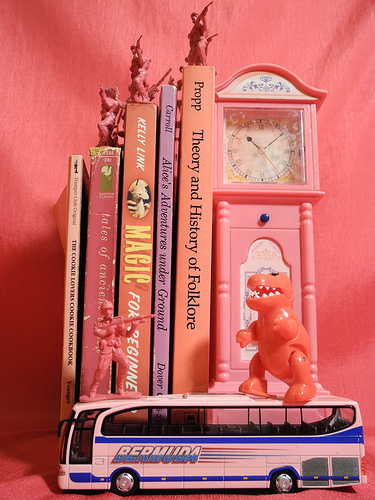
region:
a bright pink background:
[2, 0, 372, 498]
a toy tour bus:
[54, 393, 365, 493]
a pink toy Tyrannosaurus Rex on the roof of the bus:
[235, 270, 323, 415]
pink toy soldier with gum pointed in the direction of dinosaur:
[78, 270, 316, 408]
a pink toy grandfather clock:
[208, 62, 330, 426]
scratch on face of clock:
[265, 113, 299, 182]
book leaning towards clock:
[172, 65, 327, 388]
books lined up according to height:
[59, 62, 214, 426]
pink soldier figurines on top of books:
[85, 1, 218, 162]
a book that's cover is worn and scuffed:
[79, 145, 122, 394]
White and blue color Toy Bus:
[55, 398, 359, 489]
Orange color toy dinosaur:
[230, 270, 309, 397]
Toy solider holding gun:
[75, 293, 150, 392]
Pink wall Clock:
[210, 60, 321, 202]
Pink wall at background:
[0, 0, 60, 425]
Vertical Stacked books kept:
[65, 66, 209, 291]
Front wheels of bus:
[108, 465, 131, 487]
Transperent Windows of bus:
[98, 405, 353, 435]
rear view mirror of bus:
[53, 412, 57, 428]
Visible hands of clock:
[244, 127, 285, 172]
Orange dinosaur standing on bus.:
[249, 267, 311, 424]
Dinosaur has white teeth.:
[246, 283, 286, 304]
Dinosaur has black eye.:
[263, 268, 292, 286]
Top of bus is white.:
[108, 380, 321, 420]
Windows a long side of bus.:
[98, 403, 347, 437]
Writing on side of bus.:
[113, 444, 201, 468]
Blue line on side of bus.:
[87, 461, 343, 494]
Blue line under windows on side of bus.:
[95, 425, 324, 457]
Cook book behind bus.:
[57, 253, 78, 405]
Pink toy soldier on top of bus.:
[83, 285, 151, 399]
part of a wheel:
[286, 476, 294, 482]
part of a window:
[219, 422, 233, 439]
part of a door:
[83, 435, 85, 452]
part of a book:
[177, 352, 191, 372]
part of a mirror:
[51, 423, 67, 429]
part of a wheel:
[117, 481, 124, 487]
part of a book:
[197, 344, 221, 362]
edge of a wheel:
[279, 461, 290, 479]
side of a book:
[188, 322, 197, 328]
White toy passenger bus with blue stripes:
[51, 384, 366, 497]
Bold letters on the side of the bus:
[110, 441, 206, 467]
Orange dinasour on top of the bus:
[233, 267, 318, 411]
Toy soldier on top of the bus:
[75, 298, 160, 407]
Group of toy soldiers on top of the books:
[89, 1, 220, 148]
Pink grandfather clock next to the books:
[205, 59, 330, 432]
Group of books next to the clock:
[56, 61, 219, 431]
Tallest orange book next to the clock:
[168, 60, 216, 394]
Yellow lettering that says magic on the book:
[120, 217, 155, 288]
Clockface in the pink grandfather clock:
[220, 102, 309, 187]